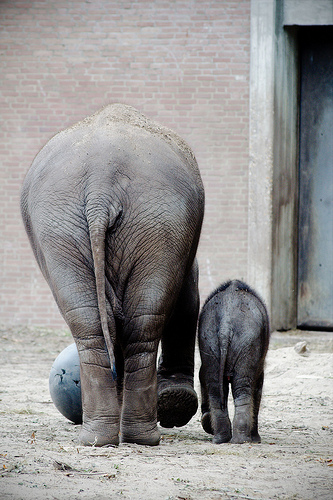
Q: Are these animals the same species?
A: Yes, all the animals are elephants.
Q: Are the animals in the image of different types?
A: No, all the animals are elephants.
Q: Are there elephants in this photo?
A: Yes, there is an elephant.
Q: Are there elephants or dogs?
A: Yes, there is an elephant.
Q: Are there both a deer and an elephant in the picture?
A: No, there is an elephant but no deer.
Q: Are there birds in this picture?
A: No, there are no birds.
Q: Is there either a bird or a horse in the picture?
A: No, there are no birds or horses.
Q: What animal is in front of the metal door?
A: The elephant is in front of the door.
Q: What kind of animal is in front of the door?
A: The animal is an elephant.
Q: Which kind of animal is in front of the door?
A: The animal is an elephant.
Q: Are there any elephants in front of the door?
A: Yes, there is an elephant in front of the door.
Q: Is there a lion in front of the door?
A: No, there is an elephant in front of the door.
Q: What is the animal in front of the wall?
A: The animal is an elephant.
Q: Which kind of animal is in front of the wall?
A: The animal is an elephant.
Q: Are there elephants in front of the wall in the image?
A: Yes, there is an elephant in front of the wall.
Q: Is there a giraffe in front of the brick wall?
A: No, there is an elephant in front of the wall.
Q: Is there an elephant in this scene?
A: Yes, there is an elephant.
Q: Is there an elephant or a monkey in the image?
A: Yes, there is an elephant.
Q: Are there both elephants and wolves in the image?
A: No, there is an elephant but no wolves.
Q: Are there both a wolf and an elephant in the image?
A: No, there is an elephant but no wolves.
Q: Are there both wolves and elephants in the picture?
A: No, there is an elephant but no wolves.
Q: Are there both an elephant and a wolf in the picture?
A: No, there is an elephant but no wolves.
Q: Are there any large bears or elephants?
A: Yes, there is a large elephant.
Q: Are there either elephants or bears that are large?
A: Yes, the elephant is large.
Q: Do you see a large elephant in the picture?
A: Yes, there is a large elephant.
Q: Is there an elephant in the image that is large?
A: Yes, there is an elephant that is large.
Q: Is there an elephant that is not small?
A: Yes, there is a large elephant.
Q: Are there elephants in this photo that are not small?
A: Yes, there is a large elephant.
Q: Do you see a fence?
A: No, there are no fences.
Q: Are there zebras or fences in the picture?
A: No, there are no fences or zebras.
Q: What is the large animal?
A: The animal is an elephant.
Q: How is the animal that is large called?
A: The animal is an elephant.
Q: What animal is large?
A: The animal is an elephant.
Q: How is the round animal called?
A: The animal is an elephant.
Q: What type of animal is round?
A: The animal is an elephant.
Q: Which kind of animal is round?
A: The animal is an elephant.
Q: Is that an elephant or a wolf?
A: That is an elephant.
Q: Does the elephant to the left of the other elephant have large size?
A: Yes, the elephant is large.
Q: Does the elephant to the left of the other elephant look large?
A: Yes, the elephant is large.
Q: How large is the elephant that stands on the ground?
A: The elephant is large.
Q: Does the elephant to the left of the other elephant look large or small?
A: The elephant is large.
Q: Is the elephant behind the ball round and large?
A: Yes, the elephant is round and large.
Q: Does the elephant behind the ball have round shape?
A: Yes, the elephant is round.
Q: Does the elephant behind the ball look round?
A: Yes, the elephant is round.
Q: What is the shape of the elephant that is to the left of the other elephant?
A: The elephant is round.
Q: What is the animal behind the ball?
A: The animal is an elephant.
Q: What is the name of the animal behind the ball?
A: The animal is an elephant.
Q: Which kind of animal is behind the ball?
A: The animal is an elephant.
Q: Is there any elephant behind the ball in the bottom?
A: Yes, there is an elephant behind the ball.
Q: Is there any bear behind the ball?
A: No, there is an elephant behind the ball.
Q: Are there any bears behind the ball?
A: No, there is an elephant behind the ball.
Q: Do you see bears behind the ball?
A: No, there is an elephant behind the ball.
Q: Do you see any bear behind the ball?
A: No, there is an elephant behind the ball.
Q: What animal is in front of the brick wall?
A: The elephant is in front of the wall.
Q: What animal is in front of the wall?
A: The elephant is in front of the wall.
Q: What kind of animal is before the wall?
A: The animal is an elephant.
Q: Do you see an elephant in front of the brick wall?
A: Yes, there is an elephant in front of the wall.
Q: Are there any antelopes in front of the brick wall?
A: No, there is an elephant in front of the wall.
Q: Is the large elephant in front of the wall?
A: Yes, the elephant is in front of the wall.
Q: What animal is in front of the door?
A: The elephant is in front of the door.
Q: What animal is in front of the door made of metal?
A: The animal is an elephant.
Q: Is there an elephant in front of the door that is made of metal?
A: Yes, there is an elephant in front of the door.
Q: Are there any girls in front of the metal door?
A: No, there is an elephant in front of the door.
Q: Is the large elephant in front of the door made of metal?
A: Yes, the elephant is in front of the door.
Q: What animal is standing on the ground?
A: The elephant is standing on the ground.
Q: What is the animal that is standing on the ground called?
A: The animal is an elephant.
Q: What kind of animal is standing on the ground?
A: The animal is an elephant.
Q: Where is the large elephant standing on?
A: The elephant is standing on the ground.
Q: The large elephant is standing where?
A: The elephant is standing on the ground.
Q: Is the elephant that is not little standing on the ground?
A: Yes, the elephant is standing on the ground.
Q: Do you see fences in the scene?
A: No, there are no fences.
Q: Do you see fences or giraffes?
A: No, there are no fences or giraffes.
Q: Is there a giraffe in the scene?
A: No, there are no giraffes.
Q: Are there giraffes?
A: No, there are no giraffes.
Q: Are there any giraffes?
A: No, there are no giraffes.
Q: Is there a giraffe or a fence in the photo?
A: No, there are no giraffes or fences.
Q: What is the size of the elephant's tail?
A: The tail is small.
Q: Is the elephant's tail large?
A: No, the tail is small.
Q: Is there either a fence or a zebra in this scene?
A: No, there are no fences or zebras.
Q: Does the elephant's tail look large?
A: Yes, the tail is large.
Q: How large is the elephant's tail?
A: The tail is large.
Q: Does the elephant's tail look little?
A: No, the tail is large.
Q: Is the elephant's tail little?
A: No, the tail is large.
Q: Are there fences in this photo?
A: No, there are no fences.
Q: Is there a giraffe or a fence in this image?
A: No, there are no fences or giraffes.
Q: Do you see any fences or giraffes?
A: No, there are no fences or giraffes.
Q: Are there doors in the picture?
A: Yes, there is a door.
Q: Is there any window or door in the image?
A: Yes, there is a door.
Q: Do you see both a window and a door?
A: No, there is a door but no windows.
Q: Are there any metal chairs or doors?
A: Yes, there is a metal door.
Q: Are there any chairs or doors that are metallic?
A: Yes, the door is metallic.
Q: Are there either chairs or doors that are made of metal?
A: Yes, the door is made of metal.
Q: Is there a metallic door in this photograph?
A: Yes, there is a metal door.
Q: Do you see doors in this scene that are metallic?
A: Yes, there is a door that is metallic.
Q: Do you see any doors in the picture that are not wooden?
A: Yes, there is a metallic door.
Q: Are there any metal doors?
A: Yes, there is a door that is made of metal.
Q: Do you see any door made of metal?
A: Yes, there is a door that is made of metal.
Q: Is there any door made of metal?
A: Yes, there is a door that is made of metal.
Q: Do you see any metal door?
A: Yes, there is a door that is made of metal.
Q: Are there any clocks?
A: No, there are no clocks.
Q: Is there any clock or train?
A: No, there are no clocks or trains.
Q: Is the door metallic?
A: Yes, the door is metallic.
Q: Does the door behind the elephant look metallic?
A: Yes, the door is metallic.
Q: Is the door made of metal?
A: Yes, the door is made of metal.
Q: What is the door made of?
A: The door is made of metal.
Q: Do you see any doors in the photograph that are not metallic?
A: No, there is a door but it is metallic.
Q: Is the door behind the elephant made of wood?
A: No, the door is made of metal.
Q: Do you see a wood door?
A: No, there is a door but it is made of metal.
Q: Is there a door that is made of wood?
A: No, there is a door but it is made of metal.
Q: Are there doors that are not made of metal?
A: No, there is a door but it is made of metal.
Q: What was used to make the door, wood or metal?
A: The door is made of metal.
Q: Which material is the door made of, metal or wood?
A: The door is made of metal.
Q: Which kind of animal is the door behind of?
A: The door is behind the elephant.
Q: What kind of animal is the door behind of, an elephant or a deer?
A: The door is behind an elephant.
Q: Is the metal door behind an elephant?
A: Yes, the door is behind an elephant.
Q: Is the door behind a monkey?
A: No, the door is behind an elephant.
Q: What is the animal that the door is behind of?
A: The animal is an elephant.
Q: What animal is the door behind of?
A: The door is behind the elephant.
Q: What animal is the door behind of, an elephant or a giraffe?
A: The door is behind an elephant.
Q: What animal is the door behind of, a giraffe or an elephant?
A: The door is behind an elephant.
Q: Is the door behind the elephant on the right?
A: Yes, the door is behind the elephant.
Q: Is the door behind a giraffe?
A: No, the door is behind the elephant.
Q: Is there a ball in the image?
A: Yes, there is a ball.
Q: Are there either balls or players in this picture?
A: Yes, there is a ball.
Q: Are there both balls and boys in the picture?
A: No, there is a ball but no boys.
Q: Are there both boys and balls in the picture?
A: No, there is a ball but no boys.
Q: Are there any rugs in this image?
A: No, there are no rugs.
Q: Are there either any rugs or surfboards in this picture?
A: No, there are no rugs or surfboards.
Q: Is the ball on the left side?
A: Yes, the ball is on the left of the image.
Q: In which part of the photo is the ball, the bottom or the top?
A: The ball is in the bottom of the image.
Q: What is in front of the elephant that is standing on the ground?
A: The ball is in front of the elephant.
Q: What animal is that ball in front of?
A: The ball is in front of the elephant.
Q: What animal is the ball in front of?
A: The ball is in front of the elephant.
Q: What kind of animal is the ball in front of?
A: The ball is in front of the elephant.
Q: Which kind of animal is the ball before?
A: The ball is in front of the elephant.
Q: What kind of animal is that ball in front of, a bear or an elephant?
A: The ball is in front of an elephant.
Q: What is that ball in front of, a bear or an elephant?
A: The ball is in front of an elephant.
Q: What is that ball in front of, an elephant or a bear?
A: The ball is in front of an elephant.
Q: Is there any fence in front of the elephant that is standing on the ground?
A: No, there is a ball in front of the elephant.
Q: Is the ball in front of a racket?
A: No, the ball is in front of the elephant.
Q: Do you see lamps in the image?
A: No, there are no lamps.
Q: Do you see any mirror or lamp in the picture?
A: No, there are no lamps or mirrors.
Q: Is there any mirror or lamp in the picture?
A: No, there are no lamps or mirrors.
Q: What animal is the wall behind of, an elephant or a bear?
A: The wall is behind an elephant.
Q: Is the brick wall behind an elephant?
A: Yes, the wall is behind an elephant.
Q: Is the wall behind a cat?
A: No, the wall is behind an elephant.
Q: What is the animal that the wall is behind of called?
A: The animal is an elephant.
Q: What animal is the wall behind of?
A: The wall is behind the elephant.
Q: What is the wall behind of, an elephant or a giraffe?
A: The wall is behind an elephant.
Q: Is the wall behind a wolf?
A: No, the wall is behind the elephant.